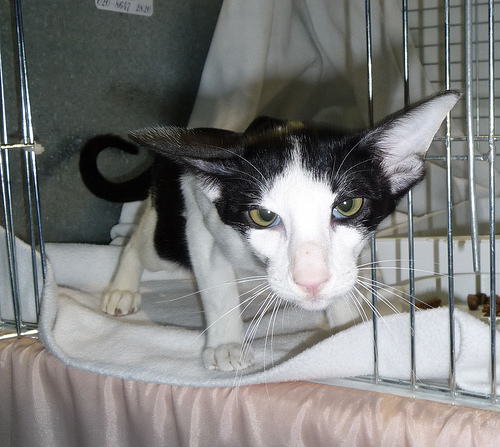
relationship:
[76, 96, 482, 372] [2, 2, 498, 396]
cat has cage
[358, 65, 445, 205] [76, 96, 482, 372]
ear of cat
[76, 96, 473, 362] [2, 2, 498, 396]
cat in cage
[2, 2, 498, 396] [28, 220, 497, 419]
cage with blanket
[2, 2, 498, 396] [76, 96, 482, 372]
cage with cat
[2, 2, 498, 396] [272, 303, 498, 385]
cage with blanket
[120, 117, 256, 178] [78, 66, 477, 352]
ear on cat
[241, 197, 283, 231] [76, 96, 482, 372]
eye on cat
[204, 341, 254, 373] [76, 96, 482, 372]
right paw on cat